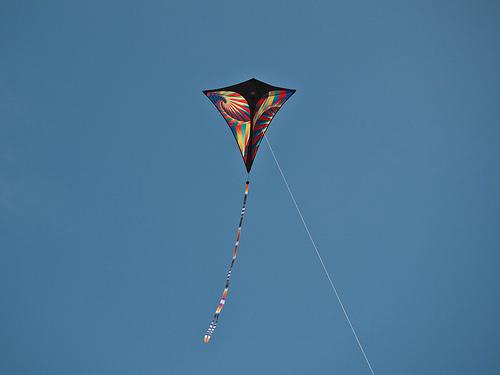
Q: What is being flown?
A: Kite.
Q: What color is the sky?
A: Blue.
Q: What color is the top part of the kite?
A: Black.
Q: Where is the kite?
A: Air.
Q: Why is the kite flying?
A: Wind.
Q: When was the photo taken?
A: Daytime.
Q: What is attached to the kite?
A: String.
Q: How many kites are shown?
A: One.